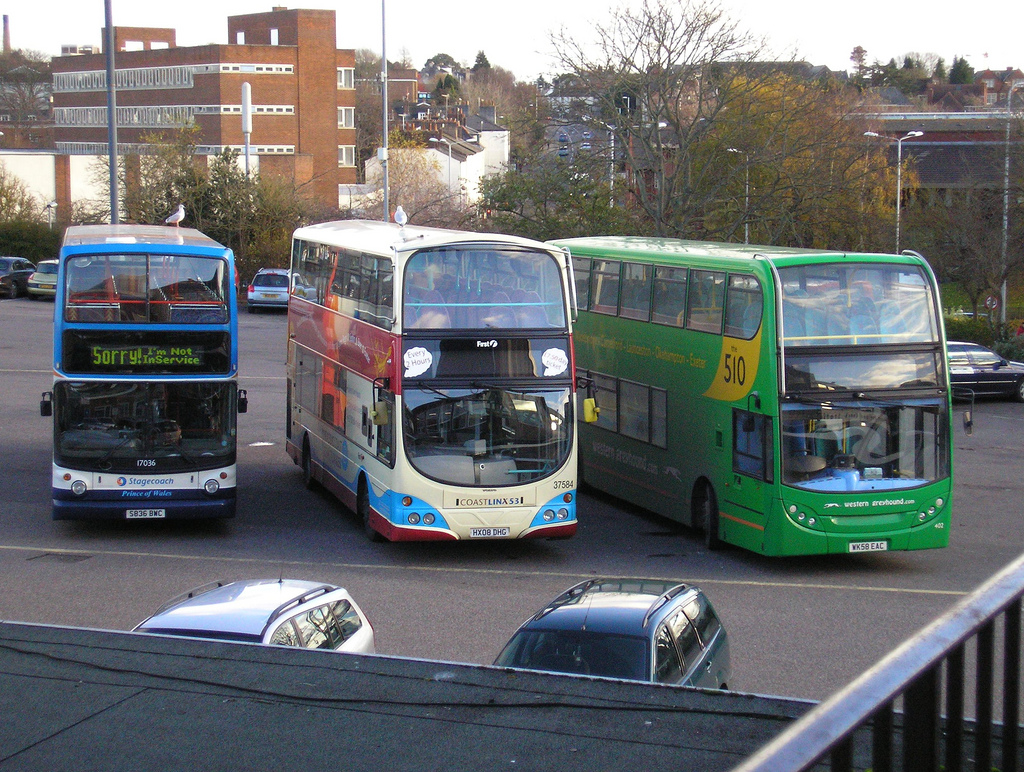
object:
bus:
[39, 223, 247, 521]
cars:
[129, 577, 726, 686]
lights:
[862, 131, 927, 256]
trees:
[545, 0, 915, 253]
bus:
[285, 219, 600, 542]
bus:
[544, 235, 955, 556]